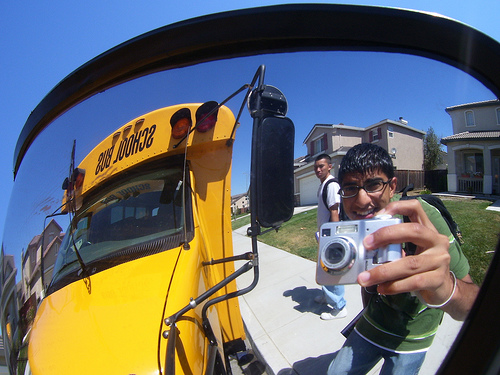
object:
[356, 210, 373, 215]
teeth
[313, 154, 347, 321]
guy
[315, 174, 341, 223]
white shirt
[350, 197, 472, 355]
shirt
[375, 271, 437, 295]
finger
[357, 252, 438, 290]
finger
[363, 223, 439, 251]
finger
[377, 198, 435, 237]
finger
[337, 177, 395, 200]
glasses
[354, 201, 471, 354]
gree shirt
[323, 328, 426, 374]
blue jeans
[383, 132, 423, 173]
wall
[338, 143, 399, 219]
head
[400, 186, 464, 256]
backpack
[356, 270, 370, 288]
finger nail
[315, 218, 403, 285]
camera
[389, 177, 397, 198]
ear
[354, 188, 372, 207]
nose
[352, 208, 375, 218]
mouth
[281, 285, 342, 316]
sneakers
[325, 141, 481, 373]
guy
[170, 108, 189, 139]
headlight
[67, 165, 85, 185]
front headlight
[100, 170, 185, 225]
reflection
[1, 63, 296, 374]
bus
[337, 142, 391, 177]
hair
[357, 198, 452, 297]
hand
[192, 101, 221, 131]
headlight